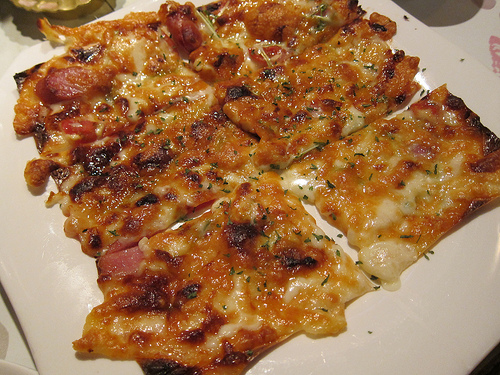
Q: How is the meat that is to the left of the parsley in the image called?
A: The meat is ham.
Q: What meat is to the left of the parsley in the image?
A: The meat is ham.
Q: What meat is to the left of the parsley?
A: The meat is ham.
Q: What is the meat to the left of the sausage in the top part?
A: The meat is ham.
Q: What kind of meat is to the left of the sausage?
A: The meat is ham.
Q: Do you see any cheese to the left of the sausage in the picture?
A: No, there is ham to the left of the sausage.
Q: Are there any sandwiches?
A: No, there are no sandwiches.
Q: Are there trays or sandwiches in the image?
A: No, there are no sandwiches or trays.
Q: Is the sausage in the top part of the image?
A: Yes, the sausage is in the top of the image.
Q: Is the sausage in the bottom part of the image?
A: No, the sausage is in the top of the image.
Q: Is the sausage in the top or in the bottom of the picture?
A: The sausage is in the top of the image.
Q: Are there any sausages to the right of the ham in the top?
A: Yes, there is a sausage to the right of the ham.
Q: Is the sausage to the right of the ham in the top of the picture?
A: Yes, the sausage is to the right of the ham.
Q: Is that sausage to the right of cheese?
A: No, the sausage is to the right of the ham.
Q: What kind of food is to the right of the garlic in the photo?
A: The food is a sausage.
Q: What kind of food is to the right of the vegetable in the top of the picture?
A: The food is a sausage.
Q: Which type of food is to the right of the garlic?
A: The food is a sausage.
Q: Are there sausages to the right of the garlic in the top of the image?
A: Yes, there is a sausage to the right of the garlic.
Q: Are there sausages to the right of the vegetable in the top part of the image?
A: Yes, there is a sausage to the right of the garlic.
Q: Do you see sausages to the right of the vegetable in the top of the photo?
A: Yes, there is a sausage to the right of the garlic.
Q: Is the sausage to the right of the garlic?
A: Yes, the sausage is to the right of the garlic.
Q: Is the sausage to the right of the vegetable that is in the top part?
A: Yes, the sausage is to the right of the garlic.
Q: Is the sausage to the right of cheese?
A: No, the sausage is to the right of the garlic.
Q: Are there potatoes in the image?
A: No, there are no potatoes.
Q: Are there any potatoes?
A: No, there are no potatoes.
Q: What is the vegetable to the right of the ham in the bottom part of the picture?
A: The vegetable is parsley.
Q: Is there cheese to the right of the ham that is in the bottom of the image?
A: No, there is parsley to the right of the ham.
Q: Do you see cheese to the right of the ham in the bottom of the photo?
A: No, there is parsley to the right of the ham.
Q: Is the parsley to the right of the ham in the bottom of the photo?
A: Yes, the parsley is to the right of the ham.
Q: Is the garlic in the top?
A: Yes, the garlic is in the top of the image.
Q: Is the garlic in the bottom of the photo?
A: No, the garlic is in the top of the image.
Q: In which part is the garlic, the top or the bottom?
A: The garlic is in the top of the image.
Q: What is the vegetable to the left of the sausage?
A: The vegetable is garlic.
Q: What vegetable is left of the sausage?
A: The vegetable is garlic.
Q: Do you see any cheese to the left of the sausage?
A: No, there is garlic to the left of the sausage.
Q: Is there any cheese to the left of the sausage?
A: No, there is garlic to the left of the sausage.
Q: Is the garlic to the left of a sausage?
A: Yes, the garlic is to the left of a sausage.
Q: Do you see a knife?
A: No, there are no knives.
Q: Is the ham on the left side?
A: Yes, the ham is on the left of the image.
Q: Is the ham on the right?
A: No, the ham is on the left of the image.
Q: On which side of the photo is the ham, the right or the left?
A: The ham is on the left of the image.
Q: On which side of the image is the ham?
A: The ham is on the left of the image.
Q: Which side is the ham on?
A: The ham is on the left of the image.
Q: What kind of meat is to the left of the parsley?
A: The meat is ham.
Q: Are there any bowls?
A: No, there are no bowls.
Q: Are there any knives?
A: No, there are no knives.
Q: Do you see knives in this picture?
A: No, there are no knives.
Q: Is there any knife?
A: No, there are no knives.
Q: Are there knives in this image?
A: No, there are no knives.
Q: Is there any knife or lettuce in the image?
A: No, there are no knives or lettuce.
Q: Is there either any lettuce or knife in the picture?
A: No, there are no knives or lettuce.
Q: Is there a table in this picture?
A: Yes, there is a table.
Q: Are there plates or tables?
A: Yes, there is a table.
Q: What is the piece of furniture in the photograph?
A: The piece of furniture is a table.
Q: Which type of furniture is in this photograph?
A: The furniture is a table.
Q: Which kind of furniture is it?
A: The piece of furniture is a table.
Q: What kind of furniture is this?
A: This is a table.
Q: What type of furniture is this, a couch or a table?
A: This is a table.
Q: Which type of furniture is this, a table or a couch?
A: This is a table.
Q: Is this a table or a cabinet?
A: This is a table.